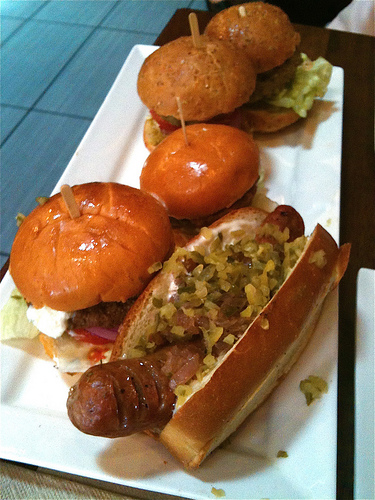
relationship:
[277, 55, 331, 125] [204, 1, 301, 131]
lettuce between bread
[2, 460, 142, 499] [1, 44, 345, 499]
mat under platter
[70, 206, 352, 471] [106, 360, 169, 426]
hotdog has splits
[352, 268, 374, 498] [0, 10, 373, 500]
plate on table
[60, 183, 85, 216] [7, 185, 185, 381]
stick in bread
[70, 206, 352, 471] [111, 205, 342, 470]
hotdog in bread